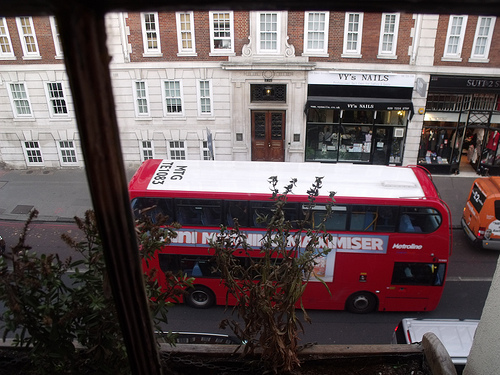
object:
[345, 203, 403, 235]
windows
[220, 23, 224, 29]
pane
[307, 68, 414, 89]
roof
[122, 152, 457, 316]
bus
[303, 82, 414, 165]
store front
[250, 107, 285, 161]
door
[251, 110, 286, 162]
frame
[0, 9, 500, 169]
wall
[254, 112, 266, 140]
windows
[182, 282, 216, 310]
tire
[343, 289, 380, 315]
tire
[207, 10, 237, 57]
window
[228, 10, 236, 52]
trim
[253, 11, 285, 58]
window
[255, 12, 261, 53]
trim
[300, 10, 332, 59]
window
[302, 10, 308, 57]
trim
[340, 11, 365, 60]
window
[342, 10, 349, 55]
trim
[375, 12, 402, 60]
window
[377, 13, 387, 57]
trim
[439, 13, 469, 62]
window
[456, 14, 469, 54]
trim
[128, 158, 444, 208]
roof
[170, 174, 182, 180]
letters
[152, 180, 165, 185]
numbers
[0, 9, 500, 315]
scene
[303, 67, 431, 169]
salon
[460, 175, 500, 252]
vehicle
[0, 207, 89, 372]
plants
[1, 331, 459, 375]
windowsill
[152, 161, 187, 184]
text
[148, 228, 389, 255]
sign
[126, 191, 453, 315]
side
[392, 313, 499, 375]
vehicle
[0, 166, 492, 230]
sidewalk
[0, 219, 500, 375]
foreground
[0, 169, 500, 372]
road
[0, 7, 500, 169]
building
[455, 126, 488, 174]
entrance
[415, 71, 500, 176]
shop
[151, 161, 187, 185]
mtg te1083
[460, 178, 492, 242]
back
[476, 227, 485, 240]
light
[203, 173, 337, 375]
plant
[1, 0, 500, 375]
window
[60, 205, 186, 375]
plant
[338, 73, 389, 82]
vy's nails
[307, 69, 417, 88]
white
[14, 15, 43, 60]
windows